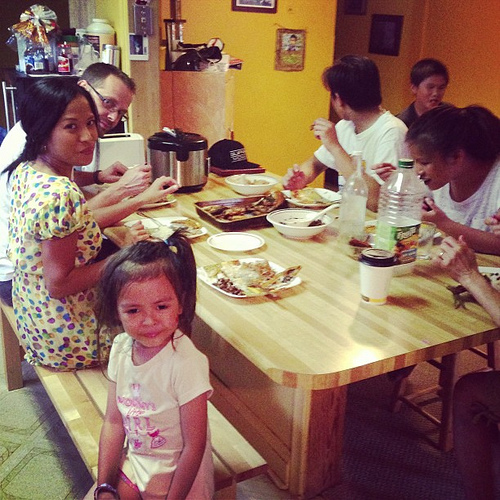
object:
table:
[100, 171, 500, 390]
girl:
[93, 225, 213, 500]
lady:
[0, 74, 149, 371]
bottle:
[339, 151, 368, 238]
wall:
[159, 0, 499, 187]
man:
[0, 62, 152, 306]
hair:
[93, 228, 198, 383]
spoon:
[282, 202, 341, 226]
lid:
[360, 247, 397, 268]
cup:
[358, 247, 396, 306]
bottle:
[374, 157, 425, 278]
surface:
[377, 185, 425, 225]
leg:
[0, 307, 24, 391]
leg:
[391, 375, 407, 415]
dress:
[4, 161, 113, 373]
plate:
[207, 230, 266, 251]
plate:
[196, 257, 304, 300]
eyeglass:
[83, 79, 130, 122]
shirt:
[105, 329, 215, 499]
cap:
[206, 139, 261, 170]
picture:
[274, 27, 306, 72]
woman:
[402, 99, 500, 256]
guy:
[283, 52, 412, 213]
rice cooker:
[146, 126, 210, 193]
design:
[228, 146, 248, 163]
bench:
[0, 297, 270, 499]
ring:
[439, 252, 444, 258]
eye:
[157, 304, 169, 311]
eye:
[125, 308, 140, 315]